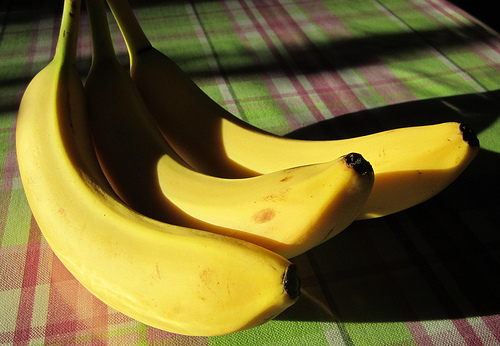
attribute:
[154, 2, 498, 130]
stripes — red green and white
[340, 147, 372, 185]
tip — black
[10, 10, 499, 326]
banana —  bruising,  some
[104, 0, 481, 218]
banana — three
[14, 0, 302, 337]
banana — yellow-ripe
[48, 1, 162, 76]
stems — green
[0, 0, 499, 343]
plaid — green and red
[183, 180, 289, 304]
bruises — small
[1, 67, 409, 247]
bananas — brown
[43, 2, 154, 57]
stem —  green 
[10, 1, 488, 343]
bananas — bunched, together, bunch, yellow , three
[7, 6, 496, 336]
table — ed and green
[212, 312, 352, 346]
stripes — green